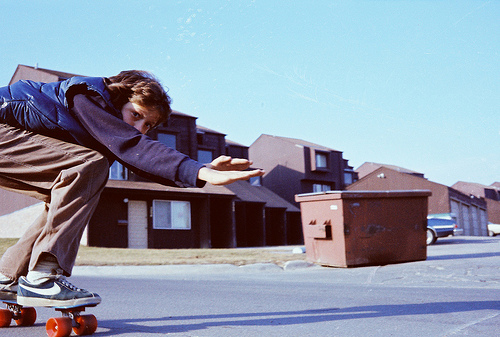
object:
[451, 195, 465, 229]
door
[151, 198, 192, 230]
window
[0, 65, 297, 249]
building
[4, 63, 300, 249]
house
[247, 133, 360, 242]
house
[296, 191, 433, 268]
brown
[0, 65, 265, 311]
boy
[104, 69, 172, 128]
hair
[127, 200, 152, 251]
door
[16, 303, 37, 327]
wheel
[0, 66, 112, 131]
vest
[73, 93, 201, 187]
arm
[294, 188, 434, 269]
dumpster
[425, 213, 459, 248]
car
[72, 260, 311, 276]
curb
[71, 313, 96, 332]
wheel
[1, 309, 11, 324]
wheel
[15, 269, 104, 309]
boy'sfoot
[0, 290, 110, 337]
skateboard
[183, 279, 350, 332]
asphalt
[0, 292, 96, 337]
board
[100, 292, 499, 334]
shadow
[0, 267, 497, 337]
ground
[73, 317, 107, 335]
wheel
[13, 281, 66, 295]
logo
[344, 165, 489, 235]
garages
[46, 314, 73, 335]
wheel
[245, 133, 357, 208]
apartments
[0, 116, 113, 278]
brown pant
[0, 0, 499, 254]
background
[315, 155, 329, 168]
window